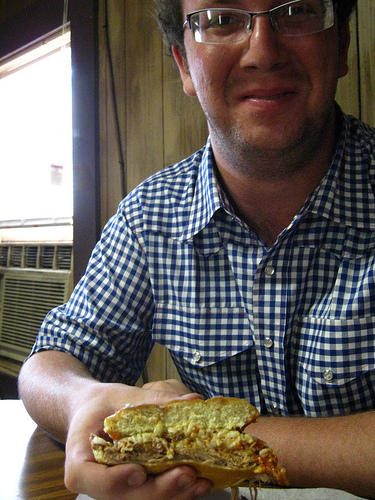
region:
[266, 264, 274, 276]
button on man's shirt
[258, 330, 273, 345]
third button from top on shirt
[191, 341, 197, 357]
pocket button on shirt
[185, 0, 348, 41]
glasses on man's face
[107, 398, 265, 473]
croissant sandwich in man's hand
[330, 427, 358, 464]
hair on the man's arm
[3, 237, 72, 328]
air conditioning unit in room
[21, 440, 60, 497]
wooden table in the room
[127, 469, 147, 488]
fingernail on the index finger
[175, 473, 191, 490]
fingernail on the middle finger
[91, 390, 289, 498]
sandwich in man's right hand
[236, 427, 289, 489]
cheese and tomato dripping out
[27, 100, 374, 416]
blue checkered button-down shirt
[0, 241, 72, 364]
air conditioner in window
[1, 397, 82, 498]
round brown wooden table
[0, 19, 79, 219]
sunlight coming from window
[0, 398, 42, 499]
sunlight reflected on table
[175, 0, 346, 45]
clear and black-rimmed glasses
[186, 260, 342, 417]
white buttons on blue and white shirt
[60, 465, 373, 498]
white napkin on table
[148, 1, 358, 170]
Man smiling for the photo.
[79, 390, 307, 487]
Man holding a sandwich.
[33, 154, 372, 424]
Man wearing a plaid blue and white shirt.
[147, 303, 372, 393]
Plaid shirt with front pockets.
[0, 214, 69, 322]
Old and dirty worn-out A/C unit.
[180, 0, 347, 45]
Man wearing prescription glasses.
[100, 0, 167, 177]
Wooden wall behind the man.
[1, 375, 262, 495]
Man's hands on the table.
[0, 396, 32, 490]
Table made of wood.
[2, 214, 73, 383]
AC unit on a wall.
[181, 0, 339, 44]
clear and black plastic rimmed eyeglasses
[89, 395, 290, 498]
pulled pork sandwich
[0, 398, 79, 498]
wood patterned Formica table top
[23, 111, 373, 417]
men's blue and white plaid shirt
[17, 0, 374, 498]
man who is holding the sandwich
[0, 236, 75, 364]
window unit style air conditioner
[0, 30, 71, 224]
glass pane window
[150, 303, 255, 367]
plaid shirts pocket flap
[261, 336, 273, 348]
white pearl snap button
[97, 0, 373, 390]
wood paneled wall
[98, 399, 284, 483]
A sandwich in the man's right hand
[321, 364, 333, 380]
A button on the shirt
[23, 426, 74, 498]
A shadow on the table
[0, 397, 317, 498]
A table beneath the sandwich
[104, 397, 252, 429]
The bun on the sandwich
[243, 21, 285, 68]
The nose of the man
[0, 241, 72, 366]
An air conditioning unit behind the man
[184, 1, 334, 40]
The man is wearing glasses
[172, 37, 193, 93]
The right ear of the man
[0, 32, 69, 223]
A window behind the man